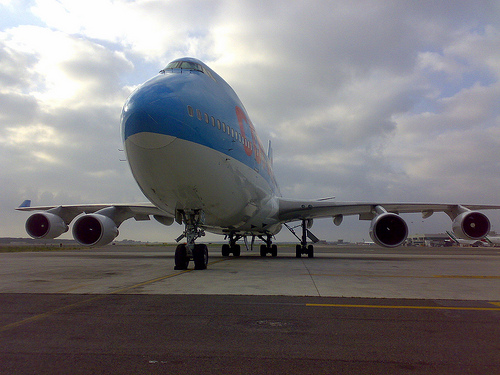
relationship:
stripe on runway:
[303, 299, 498, 312] [0, 235, 498, 372]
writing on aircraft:
[235, 108, 275, 173] [14, 53, 498, 272]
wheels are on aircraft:
[173, 242, 210, 271] [14, 53, 498, 272]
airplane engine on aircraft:
[450, 208, 491, 240] [14, 53, 498, 272]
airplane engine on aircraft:
[366, 204, 410, 248] [14, 53, 498, 272]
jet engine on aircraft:
[66, 208, 121, 247] [14, 53, 498, 272]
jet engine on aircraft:
[24, 207, 66, 242] [14, 53, 498, 272]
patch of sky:
[0, 2, 44, 28] [4, 0, 499, 232]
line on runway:
[301, 299, 483, 312] [304, 271, 443, 333]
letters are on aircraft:
[237, 96, 282, 191] [14, 53, 498, 279]